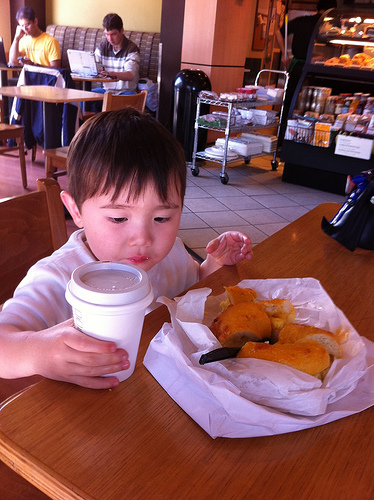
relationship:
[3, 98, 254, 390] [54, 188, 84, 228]
child has a right ear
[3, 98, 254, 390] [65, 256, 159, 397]
child holding a cup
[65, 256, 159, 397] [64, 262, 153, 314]
cup has a lid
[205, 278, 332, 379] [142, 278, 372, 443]
bread on paper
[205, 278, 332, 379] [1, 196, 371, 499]
food on table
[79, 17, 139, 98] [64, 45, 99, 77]
man using laptops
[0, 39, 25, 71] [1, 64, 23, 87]
laptop on table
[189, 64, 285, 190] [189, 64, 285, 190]
cart are in cart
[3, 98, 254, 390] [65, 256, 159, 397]
child holding cup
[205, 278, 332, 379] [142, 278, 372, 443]
bread on bag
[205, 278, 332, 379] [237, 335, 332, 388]
bread next to bread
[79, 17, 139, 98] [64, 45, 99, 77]
man on laptops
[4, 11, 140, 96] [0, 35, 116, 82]
men are using their laptops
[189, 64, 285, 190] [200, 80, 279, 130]
cart full of food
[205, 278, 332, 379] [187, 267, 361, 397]
sandwich on paper